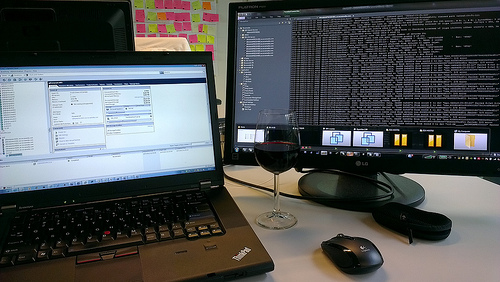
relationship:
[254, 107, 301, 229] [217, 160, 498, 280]
glass on table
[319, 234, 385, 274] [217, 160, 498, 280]
black mouse on table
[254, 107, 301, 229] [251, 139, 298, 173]
glass of wine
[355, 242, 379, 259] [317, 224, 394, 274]
logo on a computer mouse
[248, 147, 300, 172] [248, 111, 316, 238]
liquid in glass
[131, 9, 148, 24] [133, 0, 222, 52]
post it on wall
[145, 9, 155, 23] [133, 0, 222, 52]
post it on wall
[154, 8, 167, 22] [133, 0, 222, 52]
post it on wall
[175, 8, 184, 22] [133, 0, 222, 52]
post it on wall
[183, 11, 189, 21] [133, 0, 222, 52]
post it on wall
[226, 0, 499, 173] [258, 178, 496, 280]
monitor on desk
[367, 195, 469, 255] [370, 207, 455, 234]
case with zipper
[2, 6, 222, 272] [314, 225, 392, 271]
computer has mouse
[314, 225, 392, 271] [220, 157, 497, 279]
mouse on desk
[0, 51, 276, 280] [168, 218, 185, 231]
laptop has button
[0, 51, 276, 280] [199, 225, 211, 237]
laptop has button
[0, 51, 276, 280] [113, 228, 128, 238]
laptop has button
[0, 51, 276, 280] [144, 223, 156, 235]
laptop has button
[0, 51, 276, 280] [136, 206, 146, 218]
laptop has button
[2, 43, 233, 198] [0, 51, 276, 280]
screen of laptop